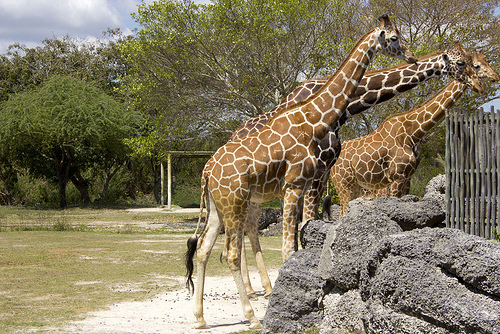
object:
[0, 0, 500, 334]
zoo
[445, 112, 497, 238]
fence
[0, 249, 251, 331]
ground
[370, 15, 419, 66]
head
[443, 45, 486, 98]
head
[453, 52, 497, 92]
head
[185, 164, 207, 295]
tail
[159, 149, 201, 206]
structure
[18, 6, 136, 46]
sky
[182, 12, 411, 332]
giraffe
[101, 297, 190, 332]
sand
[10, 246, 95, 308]
grass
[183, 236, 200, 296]
black hair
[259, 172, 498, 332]
rocks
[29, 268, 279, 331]
dirt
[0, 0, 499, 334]
enclosure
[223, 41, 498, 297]
giraffe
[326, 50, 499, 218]
giraffe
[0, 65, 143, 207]
tree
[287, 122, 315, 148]
spots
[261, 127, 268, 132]
spots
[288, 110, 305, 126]
spots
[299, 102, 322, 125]
spots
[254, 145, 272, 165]
spots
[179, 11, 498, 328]
herd